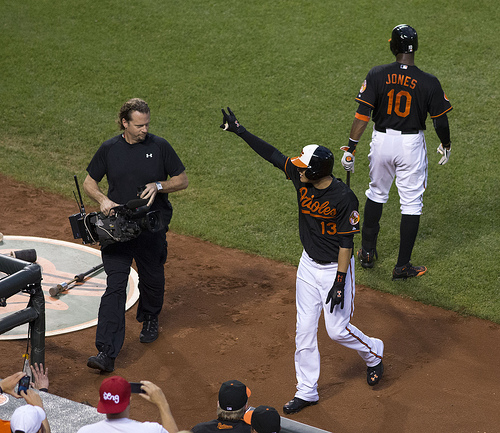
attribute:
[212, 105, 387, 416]
baseball player — saluting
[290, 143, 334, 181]
helmet — black, orange, white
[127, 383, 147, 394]
cell phone — black, sideways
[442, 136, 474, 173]
glove — white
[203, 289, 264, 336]
dirt — brown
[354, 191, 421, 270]
socks — black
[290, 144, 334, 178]
helmet — orange, white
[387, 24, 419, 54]
helmet — black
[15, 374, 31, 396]
blue cellphone — black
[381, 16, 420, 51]
cap — black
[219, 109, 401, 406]
uniform — black, orange, white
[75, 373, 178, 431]
man — picture-taking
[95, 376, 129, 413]
hat — red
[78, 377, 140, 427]
cap — red, white, backwards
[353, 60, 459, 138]
elephant — orange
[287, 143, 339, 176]
hat — orange, black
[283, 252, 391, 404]
pants — orange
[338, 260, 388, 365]
stripes — black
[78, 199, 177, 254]
camera — black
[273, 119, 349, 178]
cap — black, orange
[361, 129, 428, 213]
pants — white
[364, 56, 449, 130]
shirt — black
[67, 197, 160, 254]
camera — large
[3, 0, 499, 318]
grass section — green